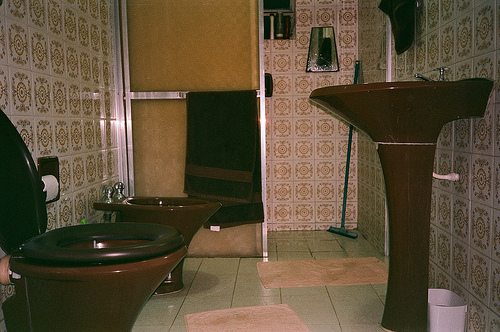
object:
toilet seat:
[0, 109, 184, 267]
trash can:
[428, 289, 468, 331]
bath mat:
[256, 257, 389, 288]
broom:
[326, 60, 360, 239]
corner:
[337, 0, 370, 235]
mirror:
[305, 26, 340, 72]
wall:
[264, 0, 357, 232]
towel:
[183, 90, 264, 230]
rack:
[131, 91, 189, 99]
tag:
[210, 225, 220, 231]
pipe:
[0, 254, 14, 285]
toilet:
[0, 110, 187, 331]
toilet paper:
[41, 174, 59, 202]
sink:
[309, 77, 494, 330]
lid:
[0, 110, 48, 256]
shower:
[121, 1, 267, 259]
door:
[119, 0, 269, 258]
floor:
[130, 228, 407, 332]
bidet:
[94, 196, 222, 293]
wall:
[1, 2, 120, 232]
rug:
[184, 303, 312, 331]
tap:
[414, 67, 450, 82]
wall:
[359, 0, 499, 331]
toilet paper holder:
[37, 156, 61, 205]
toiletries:
[263, 11, 296, 39]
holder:
[265, 36, 294, 43]